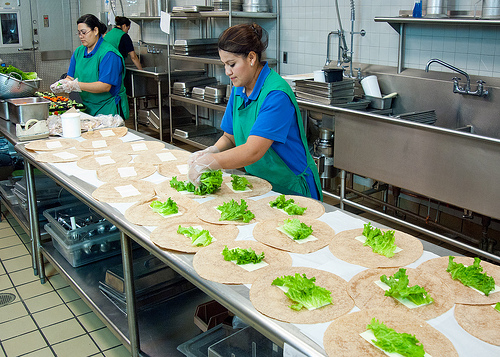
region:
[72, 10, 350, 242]
three women working in a kitchen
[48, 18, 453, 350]
women assembling food in a kitchen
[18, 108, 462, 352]
a row of tortillas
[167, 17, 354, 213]
a women making food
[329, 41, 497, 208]
a metal kitchen sink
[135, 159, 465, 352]
several tortillas with lettuce inside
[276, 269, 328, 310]
a green piece of lettuce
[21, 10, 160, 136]
kitchen worker preparing ingredients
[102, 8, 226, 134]
women washing dishes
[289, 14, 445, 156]
stack of dishes in a sink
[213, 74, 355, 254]
the apron is green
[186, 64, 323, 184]
the shirt is blue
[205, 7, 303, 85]
woman is wearing hairnet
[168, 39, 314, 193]
woman is wearing an apron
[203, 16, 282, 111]
the woman is wearing earrings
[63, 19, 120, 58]
the woman is wearing eyeglasses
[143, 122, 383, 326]
the lettuce is on tortilla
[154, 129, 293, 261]
the lettuce are green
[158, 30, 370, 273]
the woman is preparing the lettuce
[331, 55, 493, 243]
the sink is silver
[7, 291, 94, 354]
Beige tile on a floor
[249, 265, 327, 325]
Lettuce on a tortilla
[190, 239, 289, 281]
Tortilla on a counter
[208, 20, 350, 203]
Woman with brown hair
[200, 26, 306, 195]
Woman with a green apron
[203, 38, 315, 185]
Woman in a blue shirt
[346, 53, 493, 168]
Silver sink and faucet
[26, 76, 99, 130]
Vegetables on a counter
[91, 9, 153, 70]
Woman in a black shirt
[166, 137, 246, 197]
Rubber gloves on a woman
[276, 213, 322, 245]
LETTUCE ON A TORTILLA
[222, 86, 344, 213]
A GREEN APRON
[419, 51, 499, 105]
A METAL SINK FAUCET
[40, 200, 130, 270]
UTENSILS IN A PLASTIC BIN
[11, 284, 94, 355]
A WHITE TILED FLOOR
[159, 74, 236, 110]
METAL BAKING PANS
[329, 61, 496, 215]
A STAINLESS STEELE SINK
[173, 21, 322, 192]
A WOMAN PREPARING A DISH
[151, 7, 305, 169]
A METAL STORAGE RACK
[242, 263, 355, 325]
A LARGE WHITE TORTILLA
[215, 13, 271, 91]
the head of the woman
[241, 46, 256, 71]
the ear of the woman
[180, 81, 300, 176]
the arm of the woman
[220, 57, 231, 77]
the nose of the woman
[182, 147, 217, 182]
the hand of the woman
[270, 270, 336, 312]
a leaf of lettuce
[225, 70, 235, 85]
the mouth of the woman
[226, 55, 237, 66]
the eye of the woman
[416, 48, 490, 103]
a metal faucet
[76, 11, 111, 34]
the black hair of the woman